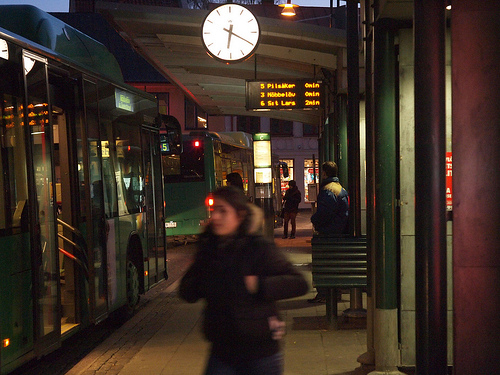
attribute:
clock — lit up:
[199, 3, 258, 63]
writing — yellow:
[258, 80, 319, 106]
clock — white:
[203, 5, 261, 59]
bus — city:
[137, 97, 271, 237]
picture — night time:
[3, 2, 485, 372]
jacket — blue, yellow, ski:
[307, 178, 357, 230]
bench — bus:
[304, 229, 372, 332]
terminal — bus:
[8, 4, 498, 371]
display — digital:
[234, 75, 335, 116]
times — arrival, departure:
[254, 80, 326, 107]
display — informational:
[249, 123, 279, 210]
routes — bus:
[252, 133, 276, 188]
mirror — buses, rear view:
[158, 110, 186, 160]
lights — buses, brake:
[202, 191, 218, 211]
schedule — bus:
[245, 75, 335, 125]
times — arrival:
[254, 82, 330, 111]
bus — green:
[1, 1, 182, 372]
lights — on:
[276, 155, 320, 187]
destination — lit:
[108, 88, 141, 113]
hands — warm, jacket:
[188, 266, 268, 306]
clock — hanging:
[195, 5, 265, 70]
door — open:
[16, 55, 86, 351]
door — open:
[22, 48, 99, 338]